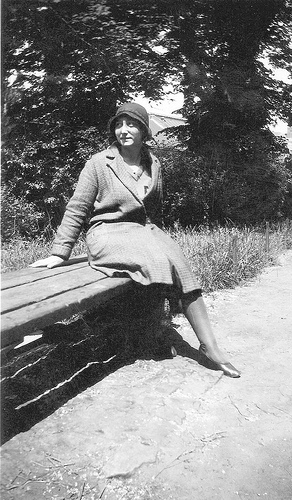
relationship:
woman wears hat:
[107, 98, 156, 153] [110, 102, 149, 124]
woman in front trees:
[29, 102, 240, 380] [3, 1, 291, 236]